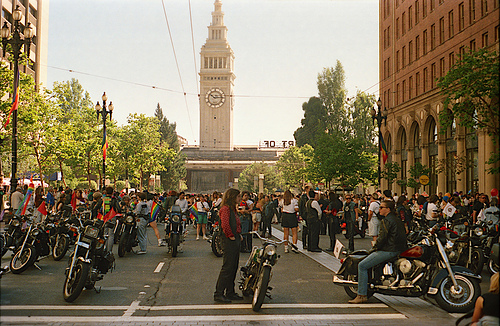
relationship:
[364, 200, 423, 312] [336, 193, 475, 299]
man sitting on motorbike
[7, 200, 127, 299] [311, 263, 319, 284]
motorbikes in road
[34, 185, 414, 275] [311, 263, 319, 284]
crowd in road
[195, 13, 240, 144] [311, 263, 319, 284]
clock tower on road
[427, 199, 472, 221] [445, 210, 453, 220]
people with flags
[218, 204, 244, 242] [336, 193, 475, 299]
woman by motorbike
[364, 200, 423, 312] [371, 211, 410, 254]
man in jacket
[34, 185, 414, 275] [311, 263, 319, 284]
crowd on road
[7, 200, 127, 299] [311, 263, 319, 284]
motorbikes on road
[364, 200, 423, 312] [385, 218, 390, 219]
man in jacket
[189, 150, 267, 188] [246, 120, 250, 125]
building in background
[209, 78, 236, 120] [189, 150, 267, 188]
clock in building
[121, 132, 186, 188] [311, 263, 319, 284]
trees by road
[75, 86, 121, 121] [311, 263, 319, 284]
street lights on road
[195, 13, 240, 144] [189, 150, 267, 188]
clock tower in building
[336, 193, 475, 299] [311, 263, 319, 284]
motorbike on road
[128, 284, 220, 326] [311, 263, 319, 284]
lines on road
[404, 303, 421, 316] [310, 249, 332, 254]
bricks on sidewalk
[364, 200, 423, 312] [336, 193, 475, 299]
man on motorbike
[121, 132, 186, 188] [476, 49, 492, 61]
trees have leaves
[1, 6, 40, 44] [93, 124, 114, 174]
lights on poles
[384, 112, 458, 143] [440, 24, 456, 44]
windows in building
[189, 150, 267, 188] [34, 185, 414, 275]
building over crowd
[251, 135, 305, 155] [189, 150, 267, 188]
letters on building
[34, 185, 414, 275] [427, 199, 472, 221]
crowd of people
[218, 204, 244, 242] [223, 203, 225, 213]
woman in red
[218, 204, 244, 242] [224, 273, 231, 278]
woman in black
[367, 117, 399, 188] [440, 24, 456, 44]
light pole by building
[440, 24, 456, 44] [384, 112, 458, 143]
building with windows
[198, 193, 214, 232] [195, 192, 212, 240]
person in shorts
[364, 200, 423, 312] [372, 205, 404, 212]
man in sunglasses